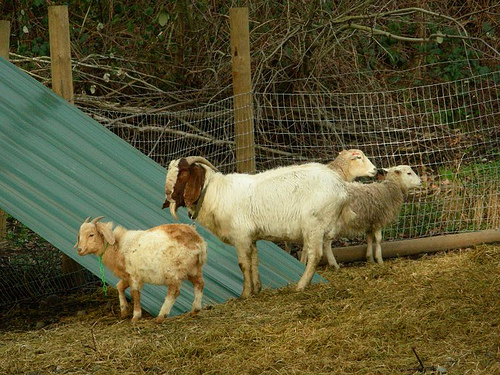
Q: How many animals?
A: 4.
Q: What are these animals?
A: Goats.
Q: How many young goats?
A: One.